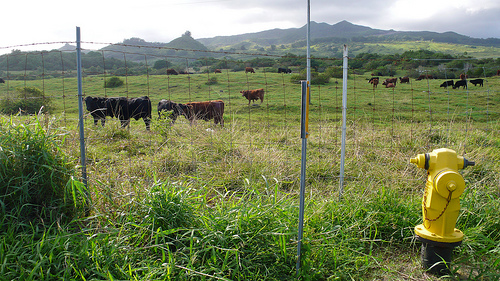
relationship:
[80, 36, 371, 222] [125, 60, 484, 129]
fence near field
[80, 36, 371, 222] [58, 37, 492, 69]
fence has barbed wire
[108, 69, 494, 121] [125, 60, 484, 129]
cows in field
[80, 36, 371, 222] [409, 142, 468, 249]
fence near hydrant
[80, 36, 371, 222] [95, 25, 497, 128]
fence has edge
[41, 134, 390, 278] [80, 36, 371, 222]
grass near fence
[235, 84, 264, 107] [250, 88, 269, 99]
cow has body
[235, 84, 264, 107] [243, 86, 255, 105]
cow has side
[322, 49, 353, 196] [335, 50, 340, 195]
pole has edge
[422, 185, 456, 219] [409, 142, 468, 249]
chain on hydrant